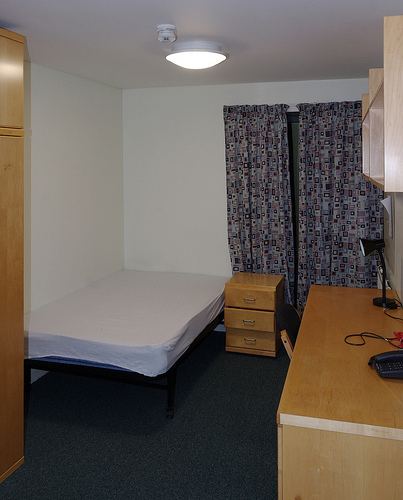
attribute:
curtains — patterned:
[217, 99, 373, 310]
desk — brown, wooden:
[276, 279, 402, 497]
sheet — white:
[30, 267, 239, 375]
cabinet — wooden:
[222, 275, 282, 357]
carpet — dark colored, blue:
[0, 324, 297, 498]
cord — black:
[335, 319, 384, 355]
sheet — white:
[22, 270, 231, 376]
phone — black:
[365, 348, 401, 377]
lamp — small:
[357, 237, 398, 310]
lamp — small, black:
[354, 225, 400, 308]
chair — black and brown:
[268, 298, 319, 363]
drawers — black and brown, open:
[222, 304, 277, 331]